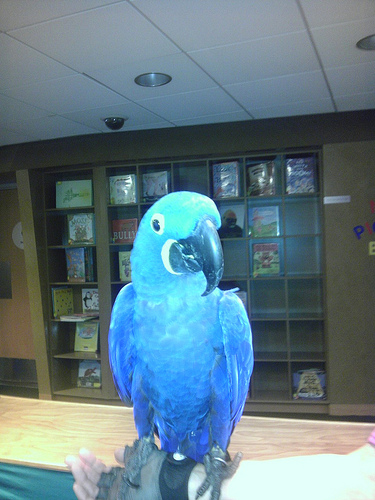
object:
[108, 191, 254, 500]
parrot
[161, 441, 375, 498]
arm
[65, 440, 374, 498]
man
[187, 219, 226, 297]
beak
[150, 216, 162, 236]
eye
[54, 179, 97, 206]
book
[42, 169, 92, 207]
hole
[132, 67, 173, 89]
light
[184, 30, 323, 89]
tile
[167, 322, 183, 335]
feathers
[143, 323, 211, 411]
belly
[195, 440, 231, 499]
foot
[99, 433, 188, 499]
glove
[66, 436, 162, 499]
hand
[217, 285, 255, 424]
wing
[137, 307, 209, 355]
chest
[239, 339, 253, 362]
feathers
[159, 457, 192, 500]
wrist band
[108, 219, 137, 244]
book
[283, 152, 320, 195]
shelf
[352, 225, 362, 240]
p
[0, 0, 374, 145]
ceiling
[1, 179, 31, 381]
door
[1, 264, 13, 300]
handle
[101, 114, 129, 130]
camera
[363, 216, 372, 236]
i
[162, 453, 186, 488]
buckle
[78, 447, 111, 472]
fingers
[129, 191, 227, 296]
head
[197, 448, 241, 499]
talon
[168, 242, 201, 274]
mouth